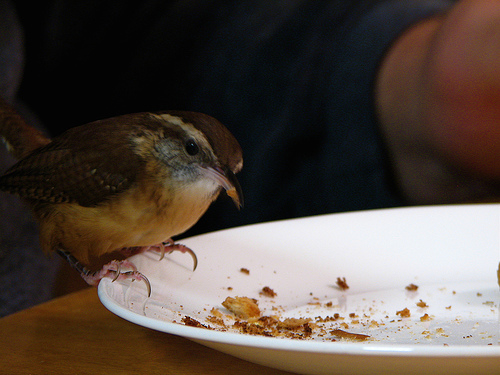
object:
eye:
[182, 138, 199, 156]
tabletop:
[2, 255, 105, 372]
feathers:
[31, 133, 119, 233]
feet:
[139, 241, 198, 273]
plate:
[93, 203, 500, 374]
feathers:
[119, 116, 188, 171]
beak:
[192, 156, 244, 209]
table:
[1, 280, 302, 375]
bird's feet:
[57, 252, 154, 303]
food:
[180, 294, 369, 337]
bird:
[0, 106, 245, 316]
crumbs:
[183, 266, 440, 340]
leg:
[56, 242, 154, 301]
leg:
[133, 234, 196, 274]